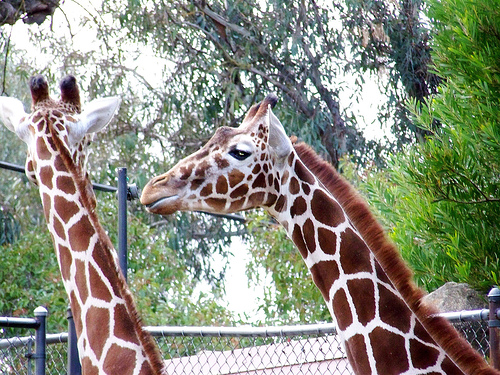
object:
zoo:
[0, 0, 498, 372]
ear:
[76, 95, 124, 133]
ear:
[0, 96, 23, 133]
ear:
[267, 104, 293, 159]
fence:
[0, 288, 499, 374]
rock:
[416, 280, 488, 314]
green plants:
[345, 0, 497, 288]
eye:
[230, 148, 252, 159]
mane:
[290, 135, 499, 374]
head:
[139, 94, 279, 213]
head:
[0, 75, 123, 186]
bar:
[0, 161, 264, 224]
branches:
[174, 0, 429, 88]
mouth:
[140, 194, 178, 210]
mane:
[50, 134, 171, 374]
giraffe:
[138, 96, 500, 375]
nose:
[152, 176, 168, 185]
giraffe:
[0, 76, 166, 374]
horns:
[242, 92, 277, 134]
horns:
[29, 75, 80, 105]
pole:
[118, 167, 127, 279]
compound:
[4, 282, 499, 374]